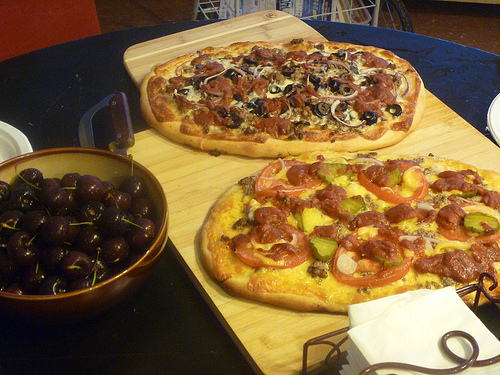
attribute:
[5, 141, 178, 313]
bowl — brown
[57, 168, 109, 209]
cherry — dark red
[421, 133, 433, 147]
ground — metal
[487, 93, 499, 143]
plate — empty, white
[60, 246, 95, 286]
cherry — dark red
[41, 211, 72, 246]
cherry — dark red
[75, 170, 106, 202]
cherry — dark red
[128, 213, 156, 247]
cherry — dark red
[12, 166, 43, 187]
cherry — dark red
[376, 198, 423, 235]
pizza topping — red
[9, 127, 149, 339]
bowl — brown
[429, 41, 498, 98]
tablecloth — blue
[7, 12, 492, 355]
table — round, dark blue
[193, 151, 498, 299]
pizza — large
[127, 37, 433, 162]
pizza — onion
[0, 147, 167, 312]
bowl — olives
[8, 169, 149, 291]
fruit — red, small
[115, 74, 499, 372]
board — wooden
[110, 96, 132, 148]
handle — brown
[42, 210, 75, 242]
cherry — dark red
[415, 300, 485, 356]
dispenser — black